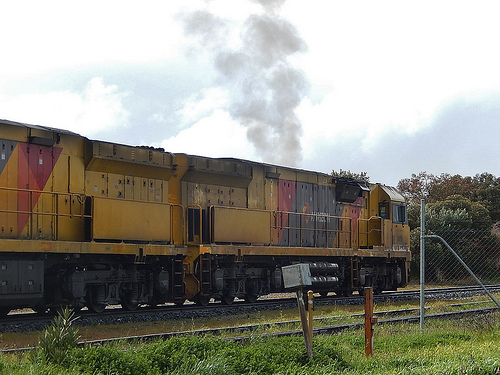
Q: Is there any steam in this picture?
A: Yes, there is steam.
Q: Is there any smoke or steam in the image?
A: Yes, there is steam.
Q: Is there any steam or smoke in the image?
A: Yes, there is steam.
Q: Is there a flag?
A: No, there are no flags.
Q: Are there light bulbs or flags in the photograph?
A: No, there are no flags or light bulbs.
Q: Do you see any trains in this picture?
A: Yes, there is a train.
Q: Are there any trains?
A: Yes, there is a train.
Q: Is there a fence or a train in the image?
A: Yes, there is a train.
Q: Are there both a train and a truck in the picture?
A: No, there is a train but no trucks.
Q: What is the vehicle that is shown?
A: The vehicle is a train.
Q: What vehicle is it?
A: The vehicle is a train.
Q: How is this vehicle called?
A: This is a train.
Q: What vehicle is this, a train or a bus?
A: This is a train.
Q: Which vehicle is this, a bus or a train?
A: This is a train.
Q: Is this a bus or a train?
A: This is a train.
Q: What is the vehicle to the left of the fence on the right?
A: The vehicle is a train.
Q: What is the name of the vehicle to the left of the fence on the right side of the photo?
A: The vehicle is a train.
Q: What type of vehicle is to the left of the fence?
A: The vehicle is a train.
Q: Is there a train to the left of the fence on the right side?
A: Yes, there is a train to the left of the fence.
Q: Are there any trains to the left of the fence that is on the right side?
A: Yes, there is a train to the left of the fence.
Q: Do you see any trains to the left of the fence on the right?
A: Yes, there is a train to the left of the fence.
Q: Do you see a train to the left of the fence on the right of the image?
A: Yes, there is a train to the left of the fence.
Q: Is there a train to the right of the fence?
A: No, the train is to the left of the fence.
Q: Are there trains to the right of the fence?
A: No, the train is to the left of the fence.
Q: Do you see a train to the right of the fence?
A: No, the train is to the left of the fence.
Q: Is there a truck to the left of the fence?
A: No, there is a train to the left of the fence.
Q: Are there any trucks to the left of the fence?
A: No, there is a train to the left of the fence.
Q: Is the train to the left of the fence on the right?
A: Yes, the train is to the left of the fence.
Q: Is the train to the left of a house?
A: No, the train is to the left of the fence.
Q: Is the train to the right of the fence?
A: No, the train is to the left of the fence.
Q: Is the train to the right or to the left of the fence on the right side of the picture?
A: The train is to the left of the fence.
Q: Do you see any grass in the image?
A: Yes, there is grass.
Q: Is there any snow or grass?
A: Yes, there is grass.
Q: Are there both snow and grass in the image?
A: No, there is grass but no snow.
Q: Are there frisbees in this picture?
A: No, there are no frisbees.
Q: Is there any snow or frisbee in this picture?
A: No, there are no frisbees or snow.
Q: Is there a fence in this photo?
A: Yes, there is a fence.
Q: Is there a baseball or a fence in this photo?
A: Yes, there is a fence.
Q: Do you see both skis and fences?
A: No, there is a fence but no skis.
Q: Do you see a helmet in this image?
A: No, there are no helmets.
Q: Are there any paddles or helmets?
A: No, there are no helmets or paddles.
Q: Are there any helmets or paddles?
A: No, there are no helmets or paddles.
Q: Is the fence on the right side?
A: Yes, the fence is on the right of the image.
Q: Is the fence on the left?
A: No, the fence is on the right of the image.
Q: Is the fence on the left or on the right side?
A: The fence is on the right of the image.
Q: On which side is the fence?
A: The fence is on the right of the image.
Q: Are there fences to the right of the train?
A: Yes, there is a fence to the right of the train.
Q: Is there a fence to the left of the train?
A: No, the fence is to the right of the train.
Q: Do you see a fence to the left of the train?
A: No, the fence is to the right of the train.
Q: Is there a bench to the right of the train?
A: No, there is a fence to the right of the train.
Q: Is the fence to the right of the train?
A: Yes, the fence is to the right of the train.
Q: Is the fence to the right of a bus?
A: No, the fence is to the right of the train.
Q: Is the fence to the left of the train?
A: No, the fence is to the right of the train.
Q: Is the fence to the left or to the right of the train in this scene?
A: The fence is to the right of the train.